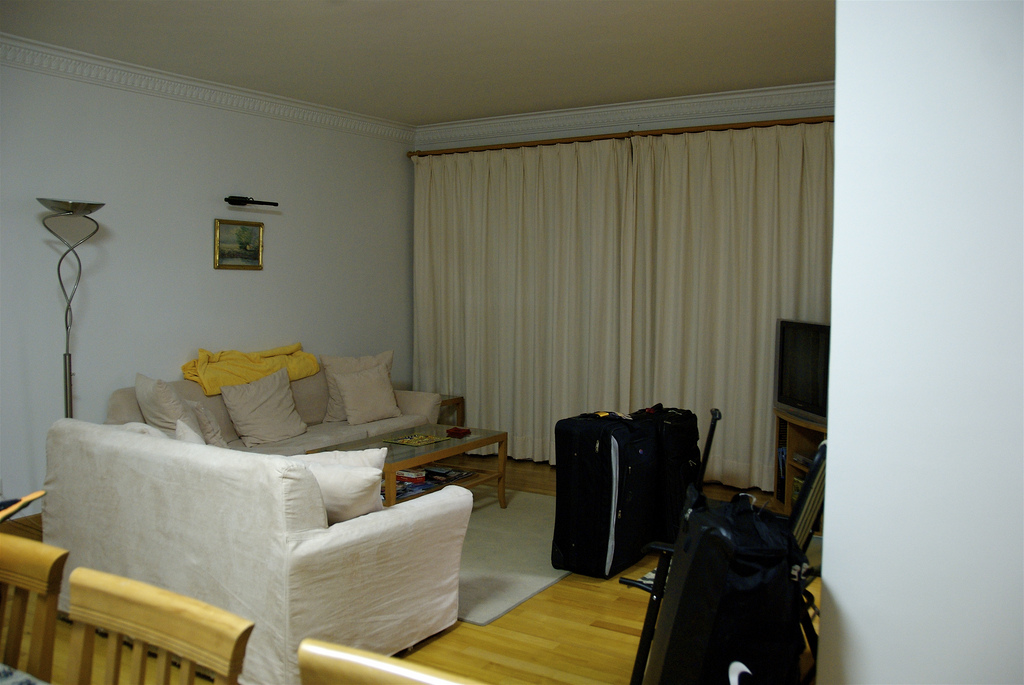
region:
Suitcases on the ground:
[532, 381, 739, 591]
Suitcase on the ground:
[532, 390, 657, 588]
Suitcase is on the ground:
[536, 393, 670, 581]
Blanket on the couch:
[178, 332, 330, 403]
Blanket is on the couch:
[181, 326, 341, 396]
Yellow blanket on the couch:
[182, 333, 329, 400]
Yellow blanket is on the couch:
[177, 334, 334, 410]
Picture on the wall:
[196, 210, 289, 281]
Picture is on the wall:
[207, 209, 274, 290]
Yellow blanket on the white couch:
[74, 297, 559, 569]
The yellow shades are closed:
[384, 59, 855, 528]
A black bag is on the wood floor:
[446, 297, 655, 683]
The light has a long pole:
[13, 164, 165, 534]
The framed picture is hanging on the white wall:
[140, 199, 381, 389]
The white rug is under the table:
[228, 293, 595, 638]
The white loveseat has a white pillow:
[33, 364, 489, 682]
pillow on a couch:
[323, 351, 403, 435]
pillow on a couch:
[222, 367, 309, 438]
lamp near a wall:
[14, 181, 158, 365]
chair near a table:
[64, 558, 261, 672]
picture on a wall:
[157, 191, 288, 283]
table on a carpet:
[453, 425, 537, 473]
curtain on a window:
[403, 160, 594, 331]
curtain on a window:
[612, 162, 805, 303]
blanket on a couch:
[181, 317, 322, 385]